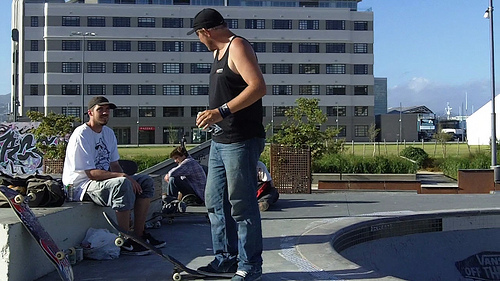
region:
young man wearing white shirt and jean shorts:
[61, 95, 169, 257]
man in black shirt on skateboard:
[186, 5, 266, 279]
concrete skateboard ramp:
[330, 213, 499, 279]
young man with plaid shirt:
[159, 145, 206, 208]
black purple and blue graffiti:
[0, 122, 72, 177]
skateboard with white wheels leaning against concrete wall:
[1, 185, 78, 280]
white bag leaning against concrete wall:
[81, 224, 123, 263]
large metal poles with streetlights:
[72, 2, 496, 167]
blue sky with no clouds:
[0, 0, 496, 86]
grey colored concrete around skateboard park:
[0, 167, 497, 277]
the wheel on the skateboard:
[13, 195, 23, 204]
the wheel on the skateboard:
[26, 192, 36, 200]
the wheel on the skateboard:
[54, 250, 64, 259]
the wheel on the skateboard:
[66, 245, 75, 255]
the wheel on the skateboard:
[114, 238, 124, 247]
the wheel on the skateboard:
[172, 271, 182, 279]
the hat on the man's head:
[86, 95, 116, 110]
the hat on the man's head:
[185, 7, 225, 35]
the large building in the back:
[10, 0, 376, 142]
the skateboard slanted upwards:
[100, 210, 205, 279]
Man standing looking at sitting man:
[179, 9, 301, 280]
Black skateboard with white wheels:
[99, 208, 211, 280]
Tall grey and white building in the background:
[0, 3, 396, 143]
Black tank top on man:
[186, 31, 278, 156]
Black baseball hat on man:
[180, 4, 230, 48]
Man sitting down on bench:
[57, 89, 189, 275]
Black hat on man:
[77, 91, 122, 121]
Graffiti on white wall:
[0, 107, 97, 199]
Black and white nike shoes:
[116, 225, 168, 272]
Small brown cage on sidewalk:
[267, 138, 327, 203]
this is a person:
[162, 9, 292, 276]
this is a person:
[54, 94, 185, 275]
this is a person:
[144, 126, 211, 220]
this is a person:
[244, 133, 304, 231]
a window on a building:
[45, 32, 92, 70]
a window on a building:
[112, 70, 133, 95]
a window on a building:
[108, 58, 125, 80]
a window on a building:
[266, 60, 288, 83]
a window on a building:
[268, 36, 308, 60]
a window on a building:
[298, 15, 317, 35]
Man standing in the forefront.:
[182, 2, 270, 277]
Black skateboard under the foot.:
[100, 212, 205, 277]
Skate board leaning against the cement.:
[0, 179, 75, 279]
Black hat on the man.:
[177, 3, 232, 54]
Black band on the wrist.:
[212, 98, 232, 120]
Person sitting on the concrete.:
[63, 84, 168, 256]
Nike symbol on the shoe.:
[117, 240, 135, 252]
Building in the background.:
[7, 7, 377, 144]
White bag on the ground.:
[80, 225, 122, 263]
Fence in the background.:
[329, 134, 476, 160]